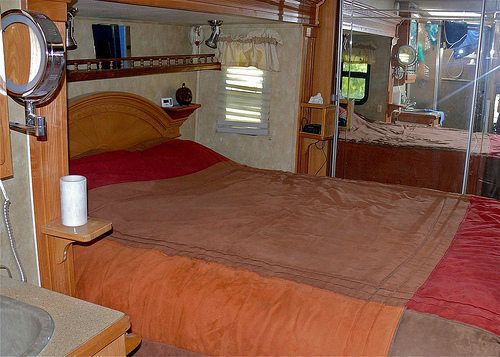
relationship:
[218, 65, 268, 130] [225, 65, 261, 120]
window letting sun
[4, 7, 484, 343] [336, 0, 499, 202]
room reflected mirror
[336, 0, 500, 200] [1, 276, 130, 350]
mirror hangs sink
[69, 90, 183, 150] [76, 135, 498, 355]
head board over bed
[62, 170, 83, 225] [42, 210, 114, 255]
candle on shelf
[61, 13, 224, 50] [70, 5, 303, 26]
lights on ceiling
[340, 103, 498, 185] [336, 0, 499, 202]
bed in mirror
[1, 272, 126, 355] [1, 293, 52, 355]
wood edge on gray sink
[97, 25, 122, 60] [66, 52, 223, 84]
book on bookshelf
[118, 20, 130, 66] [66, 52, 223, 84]
book on bookshelf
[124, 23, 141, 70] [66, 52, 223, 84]
book on bookshelf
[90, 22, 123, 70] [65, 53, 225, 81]
book sits on bookshelf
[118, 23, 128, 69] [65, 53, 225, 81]
book sits on bookshelf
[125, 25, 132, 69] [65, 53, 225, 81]
book sits on bookshelf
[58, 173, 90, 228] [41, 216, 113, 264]
candle on stand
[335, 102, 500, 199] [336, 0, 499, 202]
bed in mirror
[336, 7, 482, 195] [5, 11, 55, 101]
wall on mirror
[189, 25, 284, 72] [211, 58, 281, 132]
beige topper on window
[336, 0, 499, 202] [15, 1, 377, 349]
mirror in room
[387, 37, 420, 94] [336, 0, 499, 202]
mirror reflection in mirror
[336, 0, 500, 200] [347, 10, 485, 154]
mirror sliding doors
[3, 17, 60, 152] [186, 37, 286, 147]
mirror attached to wall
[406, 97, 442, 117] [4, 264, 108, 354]
reflection of sink